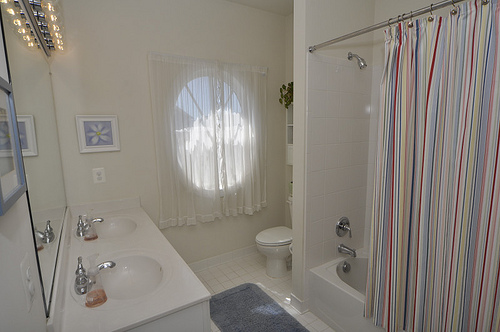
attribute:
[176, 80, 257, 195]
window — round, circular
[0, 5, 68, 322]
mirror — lighted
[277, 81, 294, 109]
plant — green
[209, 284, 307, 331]
bath rug — slate blue, gray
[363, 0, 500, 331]
shower curtain — striped, multicolored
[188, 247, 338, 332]
floor — white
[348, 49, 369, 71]
shower head — silver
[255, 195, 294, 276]
toilet — white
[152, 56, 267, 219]
curtain — white